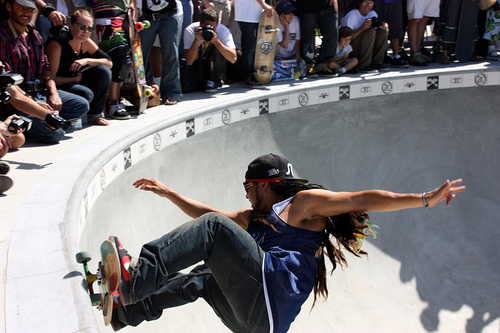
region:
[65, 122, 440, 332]
a man riding a skateboard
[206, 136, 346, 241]
a man wearing a hat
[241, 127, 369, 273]
a man with long hair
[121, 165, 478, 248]
a man with his arms stretched out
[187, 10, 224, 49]
a man holding a camera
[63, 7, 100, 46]
a woman wearing sun glasses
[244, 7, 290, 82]
a skateboard being held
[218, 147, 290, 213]
a man wearing glasses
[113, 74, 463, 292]
a concrete skateboard park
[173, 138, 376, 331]
a man wearing a blue shirt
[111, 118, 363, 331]
The man is skateboarding.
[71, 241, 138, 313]
The skateboard is heading downward.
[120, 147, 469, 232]
The mans arms are extended.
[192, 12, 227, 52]
The man is photographing the skater.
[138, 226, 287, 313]
The man is wearing jeans.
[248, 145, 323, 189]
The man's hat is black.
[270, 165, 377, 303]
The man has long hair.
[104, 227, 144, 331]
The shoes are black and red.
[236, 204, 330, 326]
The man is wearing a basketball jersey.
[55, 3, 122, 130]
The woman is watching the skater.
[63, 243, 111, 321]
green wheels on the skateboard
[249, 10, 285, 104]
person holding a skateboard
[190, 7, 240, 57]
guy taking pictures of the skateboarder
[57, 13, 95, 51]
woman is wearing sunglasses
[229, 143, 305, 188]
skater wearing is ballcap backwards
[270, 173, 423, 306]
skateboarder has long hair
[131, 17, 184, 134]
skateboard has different colored wheels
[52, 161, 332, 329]
skateboarder is doing a trick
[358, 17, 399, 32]
man is holding a camera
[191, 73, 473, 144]
edge of the skate ramp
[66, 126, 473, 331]
a skater making tricks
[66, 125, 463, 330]
skater has extended arms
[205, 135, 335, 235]
skater has a black hat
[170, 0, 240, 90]
man taking pictures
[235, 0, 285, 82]
person holds a skateboard with his right arm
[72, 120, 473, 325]
skater wears a blue tank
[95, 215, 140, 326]
skater wears red and black tennis shoes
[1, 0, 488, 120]
viewers watching a skater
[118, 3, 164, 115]
skatebaord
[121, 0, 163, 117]
skateboard has red, green and yellow wheels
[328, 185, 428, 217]
an arm of a person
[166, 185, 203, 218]
an arm of a person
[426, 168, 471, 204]
the hand of a person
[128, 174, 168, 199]
the hand of a person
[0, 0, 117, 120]
a crowd of people watching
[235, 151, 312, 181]
a black ball cap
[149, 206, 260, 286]
the leg of a person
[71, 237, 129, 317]
a skate board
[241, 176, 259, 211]
the face of a person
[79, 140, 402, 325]
a man doing a skateboard trick